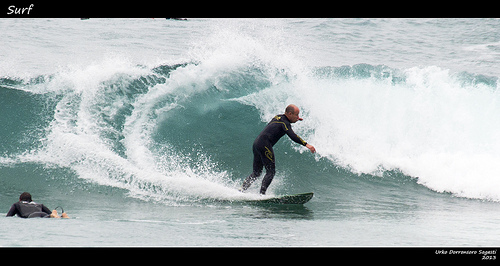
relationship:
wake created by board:
[75, 117, 170, 193] [218, 192, 314, 204]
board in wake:
[218, 192, 314, 204] [75, 117, 170, 193]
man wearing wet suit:
[238, 104, 316, 195] [241, 113, 305, 194]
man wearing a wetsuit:
[238, 104, 316, 195] [239, 114, 300, 182]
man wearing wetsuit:
[238, 104, 316, 195] [247, 112, 304, 191]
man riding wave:
[238, 104, 316, 195] [7, 45, 499, 207]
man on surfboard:
[237, 99, 308, 199] [206, 182, 328, 208]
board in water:
[218, 192, 314, 204] [0, 18, 499, 248]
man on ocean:
[238, 104, 316, 195] [327, 80, 409, 172]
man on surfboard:
[238, 104, 316, 195] [207, 186, 317, 211]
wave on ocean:
[7, 45, 499, 207] [2, 17, 498, 259]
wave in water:
[7, 45, 499, 207] [0, 18, 499, 248]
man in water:
[238, 104, 316, 195] [0, 18, 499, 248]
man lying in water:
[4, 192, 69, 218] [0, 18, 499, 248]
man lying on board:
[10, 186, 86, 223] [13, 207, 66, 229]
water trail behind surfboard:
[28, 55, 248, 204] [203, 188, 313, 205]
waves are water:
[0, 57, 498, 177] [13, 25, 494, 205]